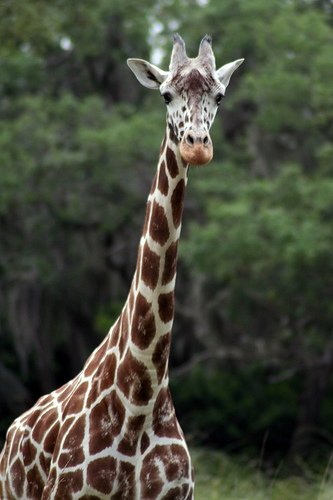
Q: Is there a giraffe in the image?
A: Yes, there is a giraffe.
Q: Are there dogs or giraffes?
A: Yes, there is a giraffe.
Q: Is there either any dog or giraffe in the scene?
A: Yes, there is a giraffe.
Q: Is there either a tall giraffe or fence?
A: Yes, there is a tall giraffe.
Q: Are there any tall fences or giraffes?
A: Yes, there is a tall giraffe.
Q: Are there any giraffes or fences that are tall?
A: Yes, the giraffe is tall.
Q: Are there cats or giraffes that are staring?
A: Yes, the giraffe is staring.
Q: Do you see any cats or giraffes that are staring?
A: Yes, the giraffe is staring.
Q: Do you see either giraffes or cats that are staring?
A: Yes, the giraffe is staring.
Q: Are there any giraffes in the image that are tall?
A: Yes, there is a tall giraffe.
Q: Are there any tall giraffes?
A: Yes, there is a tall giraffe.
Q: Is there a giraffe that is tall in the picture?
A: Yes, there is a tall giraffe.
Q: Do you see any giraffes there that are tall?
A: Yes, there is a giraffe that is tall.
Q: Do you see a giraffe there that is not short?
A: Yes, there is a tall giraffe.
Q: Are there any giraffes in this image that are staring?
A: Yes, there is a giraffe that is staring.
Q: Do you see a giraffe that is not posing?
A: Yes, there is a giraffe that is staring .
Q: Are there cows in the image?
A: No, there are no cows.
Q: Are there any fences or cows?
A: No, there are no cows or fences.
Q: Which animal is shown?
A: The animal is a giraffe.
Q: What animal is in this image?
A: The animal is a giraffe.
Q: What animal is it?
A: The animal is a giraffe.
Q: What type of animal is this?
A: This is a giraffe.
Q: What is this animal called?
A: This is a giraffe.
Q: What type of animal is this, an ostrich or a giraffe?
A: This is a giraffe.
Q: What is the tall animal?
A: The animal is a giraffe.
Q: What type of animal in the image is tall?
A: The animal is a giraffe.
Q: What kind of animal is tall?
A: The animal is a giraffe.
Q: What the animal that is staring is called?
A: The animal is a giraffe.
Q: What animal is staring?
A: The animal is a giraffe.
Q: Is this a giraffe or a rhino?
A: This is a giraffe.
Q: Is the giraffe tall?
A: Yes, the giraffe is tall.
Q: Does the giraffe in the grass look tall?
A: Yes, the giraffe is tall.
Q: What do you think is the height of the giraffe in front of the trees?
A: The giraffe is tall.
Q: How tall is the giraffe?
A: The giraffe is tall.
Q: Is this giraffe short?
A: No, the giraffe is tall.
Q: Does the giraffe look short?
A: No, the giraffe is tall.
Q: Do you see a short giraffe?
A: No, there is a giraffe but it is tall.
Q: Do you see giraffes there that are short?
A: No, there is a giraffe but it is tall.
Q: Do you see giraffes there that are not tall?
A: No, there is a giraffe but it is tall.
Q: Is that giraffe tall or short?
A: The giraffe is tall.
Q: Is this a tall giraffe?
A: Yes, this is a tall giraffe.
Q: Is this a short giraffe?
A: No, this is a tall giraffe.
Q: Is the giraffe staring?
A: Yes, the giraffe is staring.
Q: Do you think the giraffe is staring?
A: Yes, the giraffe is staring.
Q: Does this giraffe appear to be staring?
A: Yes, the giraffe is staring.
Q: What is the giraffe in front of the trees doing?
A: The giraffe is staring.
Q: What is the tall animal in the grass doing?
A: The giraffe is staring.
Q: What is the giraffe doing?
A: The giraffe is staring.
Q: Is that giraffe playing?
A: No, the giraffe is staring.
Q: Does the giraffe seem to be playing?
A: No, the giraffe is staring.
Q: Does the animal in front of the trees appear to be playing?
A: No, the giraffe is staring.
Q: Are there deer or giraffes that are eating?
A: No, there is a giraffe but it is staring.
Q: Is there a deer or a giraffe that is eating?
A: No, there is a giraffe but it is staring.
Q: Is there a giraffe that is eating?
A: No, there is a giraffe but it is staring.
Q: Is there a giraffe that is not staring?
A: No, there is a giraffe but it is staring.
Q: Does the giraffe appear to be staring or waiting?
A: The giraffe is staring.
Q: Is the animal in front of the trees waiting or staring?
A: The giraffe is staring.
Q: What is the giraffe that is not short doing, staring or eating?
A: The giraffe is staring.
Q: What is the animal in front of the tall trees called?
A: The animal is a giraffe.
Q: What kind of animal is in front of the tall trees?
A: The animal is a giraffe.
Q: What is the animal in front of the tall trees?
A: The animal is a giraffe.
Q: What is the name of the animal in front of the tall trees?
A: The animal is a giraffe.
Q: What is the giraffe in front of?
A: The giraffe is in front of the trees.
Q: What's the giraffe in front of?
A: The giraffe is in front of the trees.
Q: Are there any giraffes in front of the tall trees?
A: Yes, there is a giraffe in front of the trees.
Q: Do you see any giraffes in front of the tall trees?
A: Yes, there is a giraffe in front of the trees.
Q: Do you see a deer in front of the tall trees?
A: No, there is a giraffe in front of the trees.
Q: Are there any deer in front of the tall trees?
A: No, there is a giraffe in front of the trees.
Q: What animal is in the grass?
A: The giraffe is in the grass.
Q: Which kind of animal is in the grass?
A: The animal is a giraffe.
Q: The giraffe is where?
A: The giraffe is in the grass.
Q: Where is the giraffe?
A: The giraffe is in the grass.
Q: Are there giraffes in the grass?
A: Yes, there is a giraffe in the grass.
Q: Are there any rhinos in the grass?
A: No, there is a giraffe in the grass.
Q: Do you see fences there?
A: No, there are no fences.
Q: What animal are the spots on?
A: The spots are on the giraffe.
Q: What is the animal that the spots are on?
A: The animal is a giraffe.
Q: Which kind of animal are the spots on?
A: The spots are on the giraffe.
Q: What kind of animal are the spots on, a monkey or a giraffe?
A: The spots are on a giraffe.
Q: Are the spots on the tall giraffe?
A: Yes, the spots are on the giraffe.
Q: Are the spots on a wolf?
A: No, the spots are on the giraffe.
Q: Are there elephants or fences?
A: No, there are no fences or elephants.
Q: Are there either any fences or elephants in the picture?
A: No, there are no fences or elephants.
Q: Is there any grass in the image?
A: Yes, there is grass.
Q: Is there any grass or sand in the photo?
A: Yes, there is grass.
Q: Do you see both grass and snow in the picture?
A: No, there is grass but no snow.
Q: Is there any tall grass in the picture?
A: Yes, there is tall grass.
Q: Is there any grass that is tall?
A: Yes, there is grass that is tall.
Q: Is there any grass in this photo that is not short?
A: Yes, there is tall grass.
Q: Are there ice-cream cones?
A: No, there are no ice-cream cones.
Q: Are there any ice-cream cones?
A: No, there are no ice-cream cones.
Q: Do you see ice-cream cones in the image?
A: No, there are no ice-cream cones.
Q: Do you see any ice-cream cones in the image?
A: No, there are no ice-cream cones.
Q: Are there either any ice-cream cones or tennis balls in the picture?
A: No, there are no ice-cream cones or tennis balls.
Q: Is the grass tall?
A: Yes, the grass is tall.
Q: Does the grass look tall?
A: Yes, the grass is tall.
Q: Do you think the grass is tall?
A: Yes, the grass is tall.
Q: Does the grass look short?
A: No, the grass is tall.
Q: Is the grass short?
A: No, the grass is tall.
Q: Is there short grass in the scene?
A: No, there is grass but it is tall.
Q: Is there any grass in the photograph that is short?
A: No, there is grass but it is tall.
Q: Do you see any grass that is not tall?
A: No, there is grass but it is tall.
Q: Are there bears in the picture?
A: No, there are no bears.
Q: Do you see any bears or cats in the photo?
A: No, there are no bears or cats.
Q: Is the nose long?
A: Yes, the nose is long.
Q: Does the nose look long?
A: Yes, the nose is long.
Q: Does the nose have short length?
A: No, the nose is long.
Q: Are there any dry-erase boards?
A: No, there are no dry-erase boards.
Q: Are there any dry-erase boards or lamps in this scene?
A: No, there are no dry-erase boards or lamps.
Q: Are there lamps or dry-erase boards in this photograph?
A: No, there are no dry-erase boards or lamps.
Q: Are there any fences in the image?
A: No, there are no fences.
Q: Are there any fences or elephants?
A: No, there are no fences or elephants.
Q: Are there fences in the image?
A: No, there are no fences.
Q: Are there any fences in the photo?
A: No, there are no fences.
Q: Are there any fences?
A: No, there are no fences.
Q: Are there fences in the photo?
A: No, there are no fences.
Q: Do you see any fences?
A: No, there are no fences.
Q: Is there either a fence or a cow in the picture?
A: No, there are no fences or cows.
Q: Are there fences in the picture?
A: No, there are no fences.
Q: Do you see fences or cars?
A: No, there are no fences or cars.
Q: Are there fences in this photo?
A: No, there are no fences.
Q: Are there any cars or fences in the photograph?
A: No, there are no fences or cars.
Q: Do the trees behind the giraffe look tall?
A: Yes, the trees are tall.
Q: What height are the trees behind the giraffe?
A: The trees are tall.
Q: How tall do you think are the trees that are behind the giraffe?
A: The trees are tall.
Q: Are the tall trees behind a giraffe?
A: Yes, the trees are behind a giraffe.